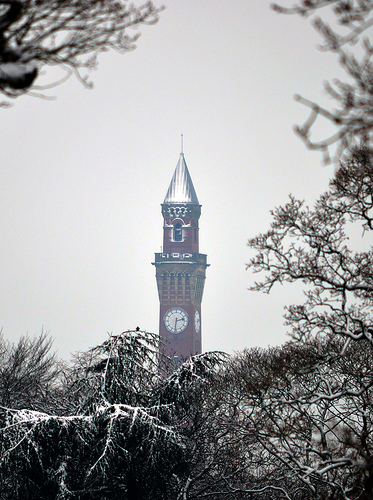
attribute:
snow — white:
[19, 406, 93, 424]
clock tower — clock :
[149, 150, 208, 339]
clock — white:
[163, 308, 188, 335]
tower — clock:
[130, 130, 263, 374]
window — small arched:
[169, 218, 188, 242]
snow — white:
[15, 395, 176, 457]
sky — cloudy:
[0, 0, 371, 360]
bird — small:
[132, 323, 142, 333]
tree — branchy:
[194, 1, 371, 497]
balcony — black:
[151, 250, 210, 265]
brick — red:
[168, 241, 194, 252]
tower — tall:
[99, 119, 263, 375]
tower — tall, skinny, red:
[150, 133, 209, 476]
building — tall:
[149, 131, 207, 446]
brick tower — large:
[142, 165, 207, 376]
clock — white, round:
[161, 307, 189, 336]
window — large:
[169, 212, 182, 243]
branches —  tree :
[275, 241, 335, 321]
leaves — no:
[285, 371, 358, 461]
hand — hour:
[175, 314, 187, 324]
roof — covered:
[158, 136, 202, 209]